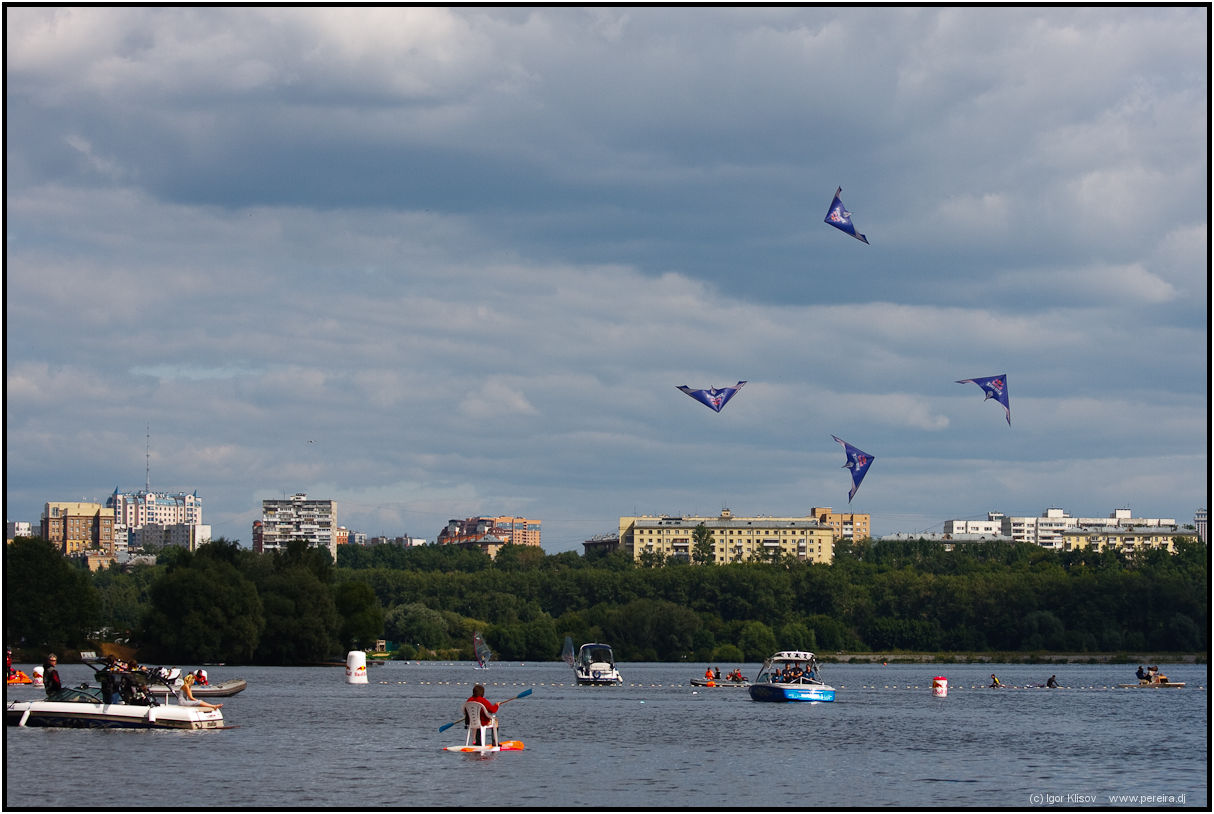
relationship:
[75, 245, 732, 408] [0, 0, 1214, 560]
clouds in blue clouds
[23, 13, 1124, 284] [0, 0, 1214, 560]
clouds in blue clouds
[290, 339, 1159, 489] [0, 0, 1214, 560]
clouds in blue clouds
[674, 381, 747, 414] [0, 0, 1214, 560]
kite in clouds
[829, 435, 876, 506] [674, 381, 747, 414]
kite in kite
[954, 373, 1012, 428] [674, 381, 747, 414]
kite in kite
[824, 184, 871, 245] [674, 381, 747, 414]
kite in kite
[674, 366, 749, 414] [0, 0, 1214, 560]
kite in clouds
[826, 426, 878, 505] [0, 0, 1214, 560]
kite in clouds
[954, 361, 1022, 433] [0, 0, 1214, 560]
kite in clouds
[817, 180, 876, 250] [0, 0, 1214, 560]
kite in clouds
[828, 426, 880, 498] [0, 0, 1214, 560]
kite in clouds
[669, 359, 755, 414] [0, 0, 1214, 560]
kite in clouds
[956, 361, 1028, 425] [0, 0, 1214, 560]
kite in clouds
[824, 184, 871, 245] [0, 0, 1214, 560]
kite in clouds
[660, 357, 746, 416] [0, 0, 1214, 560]
kite in clouds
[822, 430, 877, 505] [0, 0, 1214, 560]
kite in clouds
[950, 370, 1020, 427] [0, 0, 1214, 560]
kite in clouds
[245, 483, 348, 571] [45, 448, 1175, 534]
building in distance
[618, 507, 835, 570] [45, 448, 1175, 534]
building in distance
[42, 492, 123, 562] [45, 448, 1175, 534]
building in distance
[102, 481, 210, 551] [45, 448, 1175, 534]
building in distance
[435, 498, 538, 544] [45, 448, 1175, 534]
building in distance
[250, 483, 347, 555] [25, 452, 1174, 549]
building in distance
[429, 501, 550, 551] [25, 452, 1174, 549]
building in distance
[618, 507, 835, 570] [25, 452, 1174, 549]
building in distance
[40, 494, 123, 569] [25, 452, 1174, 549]
building in distance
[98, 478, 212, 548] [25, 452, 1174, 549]
building in distance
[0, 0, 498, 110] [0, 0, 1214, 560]
cloud covered clouds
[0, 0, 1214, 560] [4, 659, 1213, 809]
clouds above river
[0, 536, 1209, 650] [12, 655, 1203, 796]
trees beside river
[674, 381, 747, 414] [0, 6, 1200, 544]
kite in sky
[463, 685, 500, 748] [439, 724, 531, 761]
man sitting in boat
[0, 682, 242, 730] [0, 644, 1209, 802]
barge floating in water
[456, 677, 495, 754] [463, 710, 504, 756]
man sitting on chair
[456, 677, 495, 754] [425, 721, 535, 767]
man holding paddle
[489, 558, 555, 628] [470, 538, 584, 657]
leaves are on tree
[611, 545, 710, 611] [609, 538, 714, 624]
leaves are on tree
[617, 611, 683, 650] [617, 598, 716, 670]
leaves are on tree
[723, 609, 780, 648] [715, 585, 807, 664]
leaves are on tree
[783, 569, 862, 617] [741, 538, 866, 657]
leaves are on tree